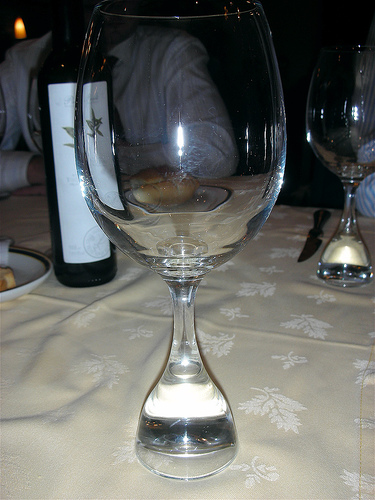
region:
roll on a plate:
[115, 157, 201, 207]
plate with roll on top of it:
[123, 157, 233, 219]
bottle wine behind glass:
[34, 5, 144, 299]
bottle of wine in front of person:
[23, 2, 142, 296]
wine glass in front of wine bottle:
[72, 5, 292, 493]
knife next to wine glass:
[298, 207, 324, 268]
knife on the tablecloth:
[297, 204, 327, 273]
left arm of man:
[140, 24, 243, 220]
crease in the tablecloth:
[24, 298, 373, 395]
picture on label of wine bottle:
[48, 114, 110, 155]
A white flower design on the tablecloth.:
[72, 349, 130, 394]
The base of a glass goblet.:
[134, 366, 240, 481]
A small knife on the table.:
[292, 201, 332, 271]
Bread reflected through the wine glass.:
[126, 167, 235, 214]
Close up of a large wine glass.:
[61, 3, 291, 286]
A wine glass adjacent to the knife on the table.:
[298, 27, 374, 290]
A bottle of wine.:
[30, 22, 113, 289]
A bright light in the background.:
[11, 15, 28, 40]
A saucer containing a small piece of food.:
[1, 237, 52, 299]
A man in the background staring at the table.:
[3, 4, 243, 209]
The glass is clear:
[57, 32, 368, 290]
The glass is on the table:
[92, 403, 279, 498]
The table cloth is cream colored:
[244, 343, 355, 444]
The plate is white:
[1, 232, 73, 326]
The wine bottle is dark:
[31, 226, 130, 295]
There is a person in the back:
[13, 18, 281, 178]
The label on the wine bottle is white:
[56, 228, 124, 286]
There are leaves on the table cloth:
[223, 380, 354, 470]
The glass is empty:
[56, 110, 268, 264]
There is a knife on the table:
[288, 203, 373, 308]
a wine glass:
[307, 30, 373, 287]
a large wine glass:
[71, 0, 287, 478]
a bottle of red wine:
[37, 0, 120, 286]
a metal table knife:
[293, 202, 333, 267]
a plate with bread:
[2, 238, 56, 309]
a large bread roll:
[128, 161, 203, 212]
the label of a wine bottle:
[42, 80, 115, 265]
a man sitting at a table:
[0, 0, 244, 184]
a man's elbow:
[353, 140, 373, 215]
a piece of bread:
[0, 264, 17, 299]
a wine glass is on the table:
[79, 6, 285, 483]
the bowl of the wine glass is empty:
[70, 5, 286, 285]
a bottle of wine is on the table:
[37, 1, 119, 285]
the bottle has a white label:
[34, 14, 118, 282]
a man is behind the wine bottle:
[3, 24, 240, 190]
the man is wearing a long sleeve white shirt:
[1, 18, 236, 185]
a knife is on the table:
[289, 205, 332, 269]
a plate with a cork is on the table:
[3, 243, 53, 308]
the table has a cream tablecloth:
[5, 190, 367, 499]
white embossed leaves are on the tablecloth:
[228, 285, 370, 493]